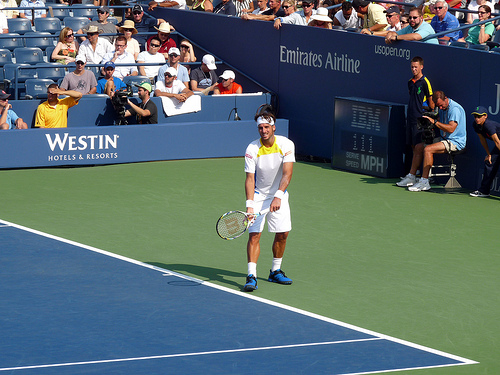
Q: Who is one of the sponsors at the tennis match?
A: Westin Hotel and Resorts.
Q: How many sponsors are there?
A: Three.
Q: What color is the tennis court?
A: Blue, white, and green.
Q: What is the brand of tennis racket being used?
A: Wimbledon.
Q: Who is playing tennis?
A: A tennis player.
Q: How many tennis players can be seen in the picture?
A: One.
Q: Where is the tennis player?
A: Behind the white line.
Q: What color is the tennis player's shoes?
A: Blue.